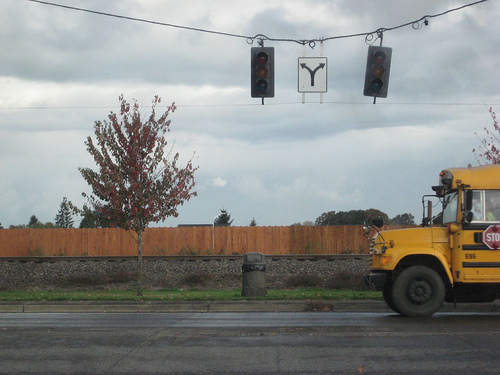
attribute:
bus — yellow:
[365, 162, 499, 321]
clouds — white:
[0, 116, 77, 185]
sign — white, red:
[479, 217, 499, 254]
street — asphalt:
[0, 313, 499, 373]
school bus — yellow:
[359, 160, 499, 322]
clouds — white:
[251, 132, 382, 168]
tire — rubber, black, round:
[382, 264, 444, 314]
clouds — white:
[187, 100, 355, 203]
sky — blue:
[191, 95, 344, 182]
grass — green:
[2, 286, 391, 310]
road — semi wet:
[1, 310, 498, 374]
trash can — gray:
[242, 252, 267, 297]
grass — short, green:
[5, 285, 377, 308]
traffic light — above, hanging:
[358, 40, 395, 105]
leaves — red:
[122, 130, 135, 146]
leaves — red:
[138, 182, 169, 193]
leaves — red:
[101, 161, 114, 178]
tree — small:
[77, 91, 204, 296]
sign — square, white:
[298, 52, 331, 96]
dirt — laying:
[115, 325, 375, 337]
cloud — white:
[63, 45, 148, 79]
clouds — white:
[14, 79, 483, 151]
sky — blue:
[3, 1, 484, 221]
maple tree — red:
[64, 91, 202, 301]